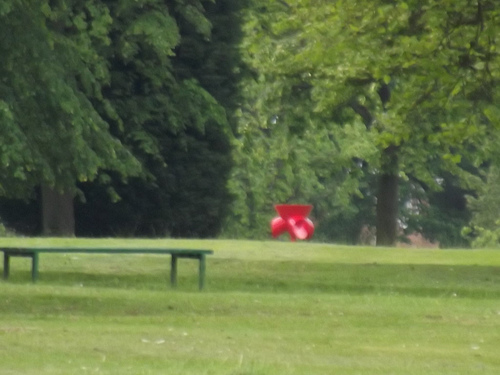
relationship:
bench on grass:
[2, 248, 213, 289] [2, 237, 500, 374]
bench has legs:
[2, 248, 213, 289] [171, 255, 206, 288]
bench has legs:
[2, 248, 213, 289] [4, 254, 38, 283]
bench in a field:
[2, 248, 213, 289] [0, 2, 499, 373]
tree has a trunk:
[0, 2, 223, 238] [39, 159, 77, 238]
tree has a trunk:
[281, 6, 466, 245] [376, 151, 399, 248]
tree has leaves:
[281, 6, 466, 245] [329, 17, 454, 149]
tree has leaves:
[0, 2, 223, 238] [19, 37, 163, 135]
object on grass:
[271, 204, 314, 242] [2, 237, 500, 374]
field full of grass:
[0, 2, 499, 373] [2, 237, 500, 374]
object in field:
[271, 204, 314, 242] [0, 2, 499, 373]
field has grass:
[0, 2, 499, 373] [2, 237, 500, 374]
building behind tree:
[402, 223, 441, 247] [281, 6, 466, 245]